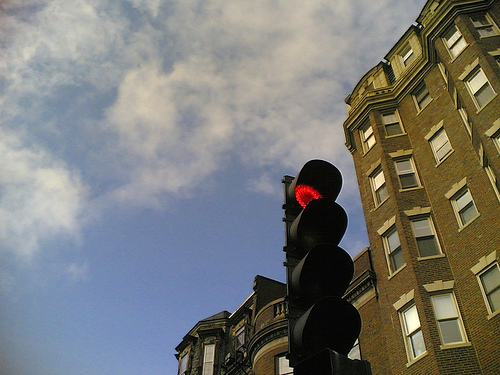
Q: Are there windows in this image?
A: Yes, there is a window.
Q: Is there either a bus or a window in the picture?
A: Yes, there is a window.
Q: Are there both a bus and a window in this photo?
A: No, there is a window but no buses.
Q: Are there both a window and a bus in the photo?
A: No, there is a window but no buses.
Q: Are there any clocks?
A: No, there are no clocks.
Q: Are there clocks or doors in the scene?
A: No, there are no clocks or doors.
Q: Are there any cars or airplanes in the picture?
A: No, there are no cars or airplanes.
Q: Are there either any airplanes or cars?
A: No, there are no cars or airplanes.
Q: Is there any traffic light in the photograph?
A: Yes, there is a traffic light.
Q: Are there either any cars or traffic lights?
A: Yes, there is a traffic light.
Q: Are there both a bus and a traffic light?
A: No, there is a traffic light but no buses.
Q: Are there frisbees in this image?
A: No, there are no frisbees.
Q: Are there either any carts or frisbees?
A: No, there are no frisbees or carts.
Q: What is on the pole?
A: The traffic light is on the pole.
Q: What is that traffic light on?
A: The traffic light is on the pole.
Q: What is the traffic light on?
A: The traffic light is on the pole.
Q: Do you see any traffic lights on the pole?
A: Yes, there is a traffic light on the pole.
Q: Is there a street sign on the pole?
A: No, there is a traffic light on the pole.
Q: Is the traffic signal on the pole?
A: Yes, the traffic signal is on the pole.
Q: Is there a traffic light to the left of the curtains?
A: Yes, there is a traffic light to the left of the curtains.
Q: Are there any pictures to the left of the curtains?
A: No, there is a traffic light to the left of the curtains.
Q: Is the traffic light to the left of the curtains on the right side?
A: Yes, the traffic light is to the left of the curtains.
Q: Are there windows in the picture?
A: Yes, there is a window.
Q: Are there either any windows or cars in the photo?
A: Yes, there is a window.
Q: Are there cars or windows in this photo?
A: Yes, there is a window.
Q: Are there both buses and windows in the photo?
A: No, there is a window but no buses.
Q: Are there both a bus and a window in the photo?
A: No, there is a window but no buses.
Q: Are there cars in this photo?
A: No, there are no cars.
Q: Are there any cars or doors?
A: No, there are no cars or doors.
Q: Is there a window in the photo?
A: Yes, there is a window.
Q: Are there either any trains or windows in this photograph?
A: Yes, there is a window.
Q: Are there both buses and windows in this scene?
A: No, there is a window but no buses.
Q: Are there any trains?
A: No, there are no trains.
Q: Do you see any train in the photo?
A: No, there are no trains.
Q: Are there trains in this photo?
A: No, there are no trains.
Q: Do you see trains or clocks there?
A: No, there are no trains or clocks.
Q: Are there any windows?
A: Yes, there is a window.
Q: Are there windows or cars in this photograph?
A: Yes, there is a window.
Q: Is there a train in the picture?
A: No, there are no trains.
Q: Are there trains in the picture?
A: No, there are no trains.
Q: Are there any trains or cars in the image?
A: No, there are no trains or cars.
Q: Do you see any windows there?
A: Yes, there is a window.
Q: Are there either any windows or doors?
A: Yes, there is a window.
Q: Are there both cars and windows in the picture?
A: No, there is a window but no cars.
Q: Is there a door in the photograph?
A: No, there are no doors.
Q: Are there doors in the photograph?
A: No, there are no doors.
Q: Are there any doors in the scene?
A: No, there are no doors.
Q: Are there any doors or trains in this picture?
A: No, there are no doors or trains.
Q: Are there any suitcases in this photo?
A: No, there are no suitcases.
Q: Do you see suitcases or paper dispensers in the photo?
A: No, there are no suitcases or paper dispensers.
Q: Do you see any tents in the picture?
A: No, there are no tents.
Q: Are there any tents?
A: No, there are no tents.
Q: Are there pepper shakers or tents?
A: No, there are no tents or pepper shakers.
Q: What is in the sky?
A: The clouds are in the sky.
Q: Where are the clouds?
A: The clouds are in the sky.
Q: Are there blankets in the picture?
A: No, there are no blankets.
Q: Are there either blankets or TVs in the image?
A: No, there are no blankets or tvs.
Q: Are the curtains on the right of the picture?
A: Yes, the curtains are on the right of the image.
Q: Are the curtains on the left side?
A: No, the curtains are on the right of the image.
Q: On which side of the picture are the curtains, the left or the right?
A: The curtains are on the right of the image.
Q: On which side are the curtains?
A: The curtains are on the right of the image.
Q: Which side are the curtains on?
A: The curtains are on the right of the image.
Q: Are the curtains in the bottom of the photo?
A: Yes, the curtains are in the bottom of the image.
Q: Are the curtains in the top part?
A: No, the curtains are in the bottom of the image.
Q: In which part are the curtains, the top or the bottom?
A: The curtains are in the bottom of the image.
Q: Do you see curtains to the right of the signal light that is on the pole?
A: Yes, there are curtains to the right of the traffic light.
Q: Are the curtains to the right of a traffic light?
A: Yes, the curtains are to the right of a traffic light.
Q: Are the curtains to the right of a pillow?
A: No, the curtains are to the right of a traffic light.